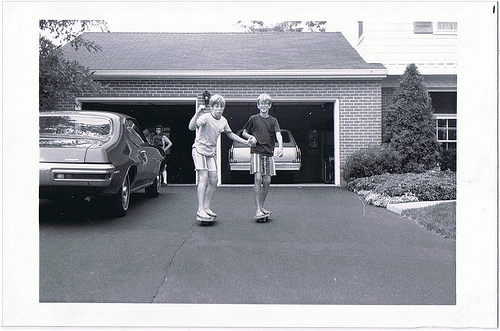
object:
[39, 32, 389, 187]
garage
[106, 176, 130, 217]
tire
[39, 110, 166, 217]
car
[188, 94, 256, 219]
boy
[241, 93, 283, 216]
boy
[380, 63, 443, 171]
pine tree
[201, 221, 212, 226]
wheels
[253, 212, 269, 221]
skateboard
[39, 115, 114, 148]
window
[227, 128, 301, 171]
car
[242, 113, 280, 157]
dark t-shirt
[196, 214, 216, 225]
skateboard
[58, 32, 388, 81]
garage roof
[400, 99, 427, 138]
leaves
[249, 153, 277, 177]
shorts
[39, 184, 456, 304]
driveway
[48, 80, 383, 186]
wall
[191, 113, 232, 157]
tshirt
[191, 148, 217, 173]
shorts